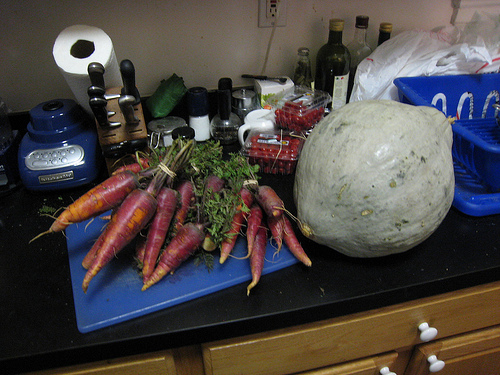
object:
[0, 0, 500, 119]
wall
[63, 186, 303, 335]
cutting board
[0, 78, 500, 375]
counter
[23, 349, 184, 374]
drawers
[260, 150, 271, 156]
tomatoes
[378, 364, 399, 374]
knobs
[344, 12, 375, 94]
bottles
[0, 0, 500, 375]
scene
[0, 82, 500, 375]
countertop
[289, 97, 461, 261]
gourd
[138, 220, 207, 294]
carrots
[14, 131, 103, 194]
bottom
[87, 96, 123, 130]
knife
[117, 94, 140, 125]
knife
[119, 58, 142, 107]
knife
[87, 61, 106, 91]
knife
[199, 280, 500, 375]
drawer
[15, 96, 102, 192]
base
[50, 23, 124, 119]
roll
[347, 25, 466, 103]
bags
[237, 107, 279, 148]
mug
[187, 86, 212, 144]
shaker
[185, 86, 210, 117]
top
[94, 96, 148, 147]
knife rack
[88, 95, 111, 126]
handle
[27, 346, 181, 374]
door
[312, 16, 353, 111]
bottle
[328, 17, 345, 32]
cap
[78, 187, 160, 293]
carrot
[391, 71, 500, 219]
dish drainer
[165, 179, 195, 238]
vegetables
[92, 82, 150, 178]
block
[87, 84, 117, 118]
knives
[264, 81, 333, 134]
box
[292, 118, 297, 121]
tomatoes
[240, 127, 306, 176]
box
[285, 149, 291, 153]
tomatoes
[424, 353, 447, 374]
handle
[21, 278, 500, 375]
cupboard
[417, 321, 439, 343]
handle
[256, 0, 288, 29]
outlet